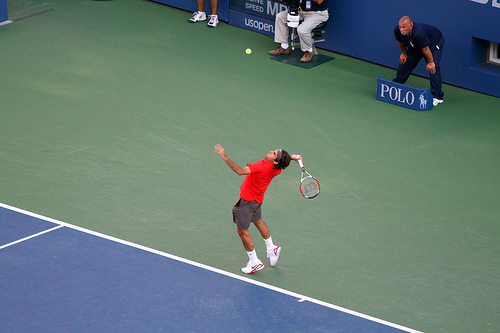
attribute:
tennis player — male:
[212, 140, 303, 274]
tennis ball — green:
[245, 49, 253, 56]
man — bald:
[390, 15, 447, 108]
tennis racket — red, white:
[293, 158, 322, 198]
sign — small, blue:
[373, 75, 434, 111]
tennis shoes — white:
[188, 7, 218, 27]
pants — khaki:
[271, 8, 327, 50]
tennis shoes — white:
[241, 245, 281, 275]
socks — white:
[244, 236, 276, 262]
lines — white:
[3, 204, 422, 331]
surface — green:
[1, 0, 499, 330]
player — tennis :
[203, 124, 327, 285]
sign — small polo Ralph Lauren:
[354, 71, 445, 119]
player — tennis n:
[214, 125, 331, 278]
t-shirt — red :
[230, 160, 288, 208]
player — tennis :
[223, 124, 328, 284]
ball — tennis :
[239, 41, 256, 59]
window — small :
[465, 40, 483, 65]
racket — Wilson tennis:
[291, 155, 338, 207]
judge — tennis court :
[266, 10, 337, 65]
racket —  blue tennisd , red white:
[294, 151, 328, 206]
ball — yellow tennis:
[243, 40, 263, 56]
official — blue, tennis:
[368, 20, 450, 89]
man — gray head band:
[211, 135, 326, 294]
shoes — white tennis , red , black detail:
[245, 241, 291, 275]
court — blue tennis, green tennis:
[7, 3, 476, 331]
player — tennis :
[188, 126, 349, 285]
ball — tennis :
[232, 39, 258, 59]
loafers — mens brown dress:
[265, 51, 312, 69]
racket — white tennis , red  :
[290, 152, 330, 205]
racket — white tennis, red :
[284, 152, 329, 202]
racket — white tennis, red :
[293, 148, 326, 203]